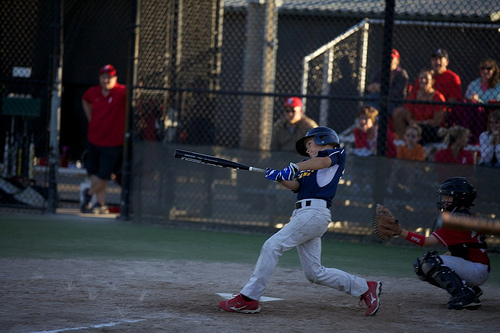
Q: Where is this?
A: This is at the field.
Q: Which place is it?
A: It is a field.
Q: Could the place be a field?
A: Yes, it is a field.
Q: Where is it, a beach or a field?
A: It is a field.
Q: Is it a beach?
A: No, it is a field.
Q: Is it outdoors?
A: Yes, it is outdoors.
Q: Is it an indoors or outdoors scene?
A: It is outdoors.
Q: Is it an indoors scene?
A: No, it is outdoors.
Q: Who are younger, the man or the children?
A: The children are younger than the man.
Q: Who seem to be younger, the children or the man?
A: The children are younger than the man.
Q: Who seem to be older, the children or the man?
A: The man are older than the children.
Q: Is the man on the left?
A: Yes, the man is on the left of the image.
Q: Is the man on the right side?
A: No, the man is on the left of the image.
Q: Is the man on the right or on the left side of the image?
A: The man is on the left of the image.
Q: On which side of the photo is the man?
A: The man is on the left of the image.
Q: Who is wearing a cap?
A: The man is wearing a cap.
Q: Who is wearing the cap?
A: The man is wearing a cap.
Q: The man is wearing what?
A: The man is wearing a cap.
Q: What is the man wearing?
A: The man is wearing a cap.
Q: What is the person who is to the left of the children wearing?
A: The man is wearing a cap.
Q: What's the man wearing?
A: The man is wearing a cap.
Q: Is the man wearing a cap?
A: Yes, the man is wearing a cap.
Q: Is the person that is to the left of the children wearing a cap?
A: Yes, the man is wearing a cap.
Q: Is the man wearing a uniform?
A: No, the man is wearing a cap.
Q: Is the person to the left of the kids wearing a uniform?
A: No, the man is wearing a cap.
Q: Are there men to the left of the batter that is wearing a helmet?
A: Yes, there is a man to the left of the batter.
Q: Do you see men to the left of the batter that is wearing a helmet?
A: Yes, there is a man to the left of the batter.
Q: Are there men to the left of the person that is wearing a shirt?
A: Yes, there is a man to the left of the batter.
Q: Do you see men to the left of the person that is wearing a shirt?
A: Yes, there is a man to the left of the batter.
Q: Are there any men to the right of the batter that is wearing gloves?
A: No, the man is to the left of the batter.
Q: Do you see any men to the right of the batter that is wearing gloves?
A: No, the man is to the left of the batter.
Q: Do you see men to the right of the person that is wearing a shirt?
A: No, the man is to the left of the batter.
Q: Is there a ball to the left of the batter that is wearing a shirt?
A: No, there is a man to the left of the batter.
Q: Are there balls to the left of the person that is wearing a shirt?
A: No, there is a man to the left of the batter.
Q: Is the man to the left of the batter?
A: Yes, the man is to the left of the batter.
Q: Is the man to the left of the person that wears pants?
A: Yes, the man is to the left of the batter.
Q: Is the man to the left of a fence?
A: No, the man is to the left of the batter.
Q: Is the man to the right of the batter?
A: No, the man is to the left of the batter.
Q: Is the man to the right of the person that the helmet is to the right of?
A: No, the man is to the left of the batter.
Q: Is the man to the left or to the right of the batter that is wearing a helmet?
A: The man is to the left of the batter.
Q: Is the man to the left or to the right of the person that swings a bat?
A: The man is to the left of the batter.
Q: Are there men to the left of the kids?
A: Yes, there is a man to the left of the kids.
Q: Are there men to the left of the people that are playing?
A: Yes, there is a man to the left of the kids.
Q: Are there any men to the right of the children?
A: No, the man is to the left of the children.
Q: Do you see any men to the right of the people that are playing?
A: No, the man is to the left of the children.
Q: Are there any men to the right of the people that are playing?
A: No, the man is to the left of the children.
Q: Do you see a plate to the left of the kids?
A: No, there is a man to the left of the kids.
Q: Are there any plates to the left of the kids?
A: No, there is a man to the left of the kids.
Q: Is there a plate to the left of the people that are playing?
A: No, there is a man to the left of the kids.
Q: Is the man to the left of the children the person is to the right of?
A: Yes, the man is to the left of the children.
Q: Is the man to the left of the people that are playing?
A: Yes, the man is to the left of the children.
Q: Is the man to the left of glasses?
A: No, the man is to the left of the children.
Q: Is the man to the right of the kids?
A: No, the man is to the left of the kids.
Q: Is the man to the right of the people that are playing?
A: No, the man is to the left of the kids.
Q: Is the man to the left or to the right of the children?
A: The man is to the left of the children.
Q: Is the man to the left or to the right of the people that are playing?
A: The man is to the left of the children.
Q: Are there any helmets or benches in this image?
A: Yes, there is a helmet.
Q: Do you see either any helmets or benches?
A: Yes, there is a helmet.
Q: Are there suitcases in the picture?
A: No, there are no suitcases.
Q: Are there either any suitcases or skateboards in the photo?
A: No, there are no suitcases or skateboards.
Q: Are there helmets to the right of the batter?
A: Yes, there is a helmet to the right of the batter.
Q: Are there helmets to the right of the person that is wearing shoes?
A: Yes, there is a helmet to the right of the batter.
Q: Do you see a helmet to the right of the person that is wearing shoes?
A: Yes, there is a helmet to the right of the batter.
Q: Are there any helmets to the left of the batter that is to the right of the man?
A: No, the helmet is to the right of the batter.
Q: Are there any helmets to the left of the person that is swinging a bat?
A: No, the helmet is to the right of the batter.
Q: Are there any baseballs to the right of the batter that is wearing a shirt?
A: No, there is a helmet to the right of the batter.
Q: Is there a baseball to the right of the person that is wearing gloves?
A: No, there is a helmet to the right of the batter.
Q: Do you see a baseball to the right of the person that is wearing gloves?
A: No, there is a helmet to the right of the batter.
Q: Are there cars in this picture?
A: No, there are no cars.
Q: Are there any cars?
A: No, there are no cars.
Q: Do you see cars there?
A: No, there are no cars.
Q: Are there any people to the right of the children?
A: Yes, there is a person to the right of the children.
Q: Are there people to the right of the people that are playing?
A: Yes, there is a person to the right of the children.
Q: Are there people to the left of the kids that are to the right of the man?
A: No, the person is to the right of the children.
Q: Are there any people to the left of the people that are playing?
A: No, the person is to the right of the children.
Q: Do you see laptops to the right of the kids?
A: No, there is a person to the right of the kids.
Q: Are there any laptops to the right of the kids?
A: No, there is a person to the right of the kids.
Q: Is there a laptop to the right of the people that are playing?
A: No, there is a person to the right of the kids.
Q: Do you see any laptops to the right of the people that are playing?
A: No, there is a person to the right of the kids.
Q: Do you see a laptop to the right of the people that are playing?
A: No, there is a person to the right of the kids.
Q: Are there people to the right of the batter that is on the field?
A: Yes, there is a person to the right of the batter.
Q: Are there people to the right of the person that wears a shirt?
A: Yes, there is a person to the right of the batter.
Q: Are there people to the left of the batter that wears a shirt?
A: No, the person is to the right of the batter.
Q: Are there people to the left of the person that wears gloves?
A: No, the person is to the right of the batter.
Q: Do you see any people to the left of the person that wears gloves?
A: No, the person is to the right of the batter.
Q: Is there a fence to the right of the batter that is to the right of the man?
A: No, there is a person to the right of the batter.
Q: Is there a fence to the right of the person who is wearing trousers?
A: No, there is a person to the right of the batter.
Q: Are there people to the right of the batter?
A: Yes, there is a person to the right of the batter.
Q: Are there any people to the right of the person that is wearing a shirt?
A: Yes, there is a person to the right of the batter.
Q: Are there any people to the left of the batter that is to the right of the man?
A: No, the person is to the right of the batter.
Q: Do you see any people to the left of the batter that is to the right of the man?
A: No, the person is to the right of the batter.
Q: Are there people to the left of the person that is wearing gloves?
A: No, the person is to the right of the batter.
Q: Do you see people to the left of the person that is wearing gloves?
A: No, the person is to the right of the batter.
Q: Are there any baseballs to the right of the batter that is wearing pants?
A: No, there is a person to the right of the batter.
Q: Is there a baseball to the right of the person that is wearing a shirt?
A: No, there is a person to the right of the batter.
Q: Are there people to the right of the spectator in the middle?
A: Yes, there is a person to the right of the spectator.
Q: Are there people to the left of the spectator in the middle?
A: No, the person is to the right of the spectator.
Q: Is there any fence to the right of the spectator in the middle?
A: No, there is a person to the right of the spectator.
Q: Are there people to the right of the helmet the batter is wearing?
A: Yes, there is a person to the right of the helmet.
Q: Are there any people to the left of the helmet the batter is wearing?
A: No, the person is to the right of the helmet.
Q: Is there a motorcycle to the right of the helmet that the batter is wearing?
A: No, there is a person to the right of the helmet.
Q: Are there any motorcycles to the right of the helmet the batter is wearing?
A: No, there is a person to the right of the helmet.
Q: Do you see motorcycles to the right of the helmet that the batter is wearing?
A: No, there is a person to the right of the helmet.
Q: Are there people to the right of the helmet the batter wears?
A: Yes, there is a person to the right of the helmet.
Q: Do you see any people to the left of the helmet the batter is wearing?
A: No, the person is to the right of the helmet.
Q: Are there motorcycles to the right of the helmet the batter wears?
A: No, there is a person to the right of the helmet.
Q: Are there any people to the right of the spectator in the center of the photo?
A: Yes, there is a person to the right of the spectator.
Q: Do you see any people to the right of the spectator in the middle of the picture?
A: Yes, there is a person to the right of the spectator.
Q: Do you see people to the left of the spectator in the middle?
A: No, the person is to the right of the spectator.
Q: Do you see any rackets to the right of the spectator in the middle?
A: No, there is a person to the right of the spectator.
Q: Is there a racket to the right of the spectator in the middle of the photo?
A: No, there is a person to the right of the spectator.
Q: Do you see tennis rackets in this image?
A: No, there are no tennis rackets.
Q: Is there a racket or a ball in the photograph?
A: No, there are no rackets or balls.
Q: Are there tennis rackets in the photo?
A: No, there are no tennis rackets.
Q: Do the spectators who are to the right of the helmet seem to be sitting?
A: Yes, the spectators are sitting.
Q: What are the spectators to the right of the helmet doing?
A: The spectators are sitting.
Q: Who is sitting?
A: The spectators are sitting.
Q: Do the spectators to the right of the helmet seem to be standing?
A: No, the spectators are sitting.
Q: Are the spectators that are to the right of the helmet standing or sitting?
A: The spectators are sitting.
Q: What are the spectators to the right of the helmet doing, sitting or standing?
A: The spectators are sitting.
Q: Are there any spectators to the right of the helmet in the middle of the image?
A: Yes, there are spectators to the right of the helmet.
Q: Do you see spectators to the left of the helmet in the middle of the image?
A: No, the spectators are to the right of the helmet.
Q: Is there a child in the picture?
A: Yes, there are children.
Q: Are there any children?
A: Yes, there are children.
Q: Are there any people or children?
A: Yes, there are children.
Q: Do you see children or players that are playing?
A: Yes, the children are playing.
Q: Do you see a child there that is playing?
A: Yes, there are children that are playing.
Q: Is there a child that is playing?
A: Yes, there are children that are playing.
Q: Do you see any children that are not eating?
A: Yes, there are children that are playing .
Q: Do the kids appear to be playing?
A: Yes, the kids are playing.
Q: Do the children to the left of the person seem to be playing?
A: Yes, the kids are playing.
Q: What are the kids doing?
A: The kids are playing.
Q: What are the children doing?
A: The kids are playing.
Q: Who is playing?
A: The kids are playing.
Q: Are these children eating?
A: No, the children are playing.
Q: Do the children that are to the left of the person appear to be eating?
A: No, the kids are playing.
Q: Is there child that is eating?
A: No, there are children but they are playing.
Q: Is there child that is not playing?
A: No, there are children but they are playing.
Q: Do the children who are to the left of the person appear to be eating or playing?
A: The children are playing.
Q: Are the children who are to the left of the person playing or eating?
A: The children are playing.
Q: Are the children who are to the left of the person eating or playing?
A: The children are playing.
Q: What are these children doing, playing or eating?
A: The children are playing.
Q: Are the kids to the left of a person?
A: Yes, the kids are to the left of a person.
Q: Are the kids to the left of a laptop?
A: No, the kids are to the left of a person.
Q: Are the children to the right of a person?
A: No, the children are to the left of a person.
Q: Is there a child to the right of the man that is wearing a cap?
A: Yes, there are children to the right of the man.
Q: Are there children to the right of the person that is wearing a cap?
A: Yes, there are children to the right of the man.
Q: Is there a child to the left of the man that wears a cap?
A: No, the children are to the right of the man.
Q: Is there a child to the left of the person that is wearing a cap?
A: No, the children are to the right of the man.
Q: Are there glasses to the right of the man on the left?
A: No, there are children to the right of the man.